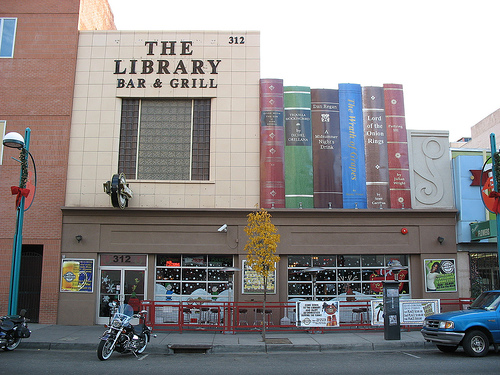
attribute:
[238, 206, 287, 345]
tree leaves — yellow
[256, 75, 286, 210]
book — big, red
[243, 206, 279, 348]
tree — small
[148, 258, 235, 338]
wall — big, painted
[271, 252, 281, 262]
leaf — yellow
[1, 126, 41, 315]
pole — blue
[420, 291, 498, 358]
blue truck — pick up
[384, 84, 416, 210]
book — big, red, painted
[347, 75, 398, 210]
book — red, big, painted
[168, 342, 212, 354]
drain — sewer opening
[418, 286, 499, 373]
vehicle — blue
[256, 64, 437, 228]
books — colored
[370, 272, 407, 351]
meter — electronic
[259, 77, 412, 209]
volumes — large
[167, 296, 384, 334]
stools — black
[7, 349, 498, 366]
road — paved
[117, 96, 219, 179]
window — large, block glass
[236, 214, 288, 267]
leaves — yellow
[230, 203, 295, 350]
tree — small, leafy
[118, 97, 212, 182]
window — large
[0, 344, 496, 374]
pavement — grey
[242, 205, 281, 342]
tree — small, thin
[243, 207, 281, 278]
leaves — yellowing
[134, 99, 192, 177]
tiles — frosted, glass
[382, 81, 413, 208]
book — red